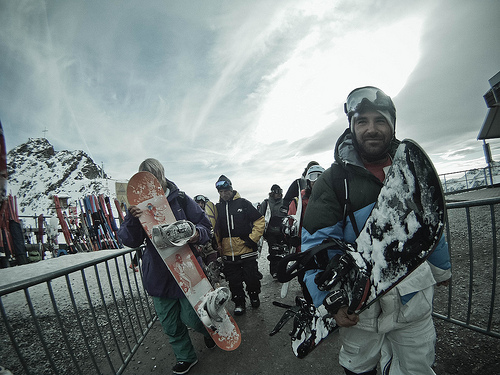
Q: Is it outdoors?
A: Yes, it is outdoors.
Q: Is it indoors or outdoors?
A: It is outdoors.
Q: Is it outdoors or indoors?
A: It is outdoors.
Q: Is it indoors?
A: No, it is outdoors.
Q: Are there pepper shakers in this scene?
A: No, there are no pepper shakers.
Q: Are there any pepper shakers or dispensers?
A: No, there are no pepper shakers or dispensers.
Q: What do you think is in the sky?
A: The clouds are in the sky.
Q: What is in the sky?
A: The clouds are in the sky.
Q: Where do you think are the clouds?
A: The clouds are in the sky.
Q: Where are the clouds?
A: The clouds are in the sky.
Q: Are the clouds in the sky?
A: Yes, the clouds are in the sky.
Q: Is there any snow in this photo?
A: Yes, there is snow.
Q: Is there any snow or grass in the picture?
A: Yes, there is snow.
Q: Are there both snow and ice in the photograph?
A: No, there is snow but no ice.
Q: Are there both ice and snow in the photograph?
A: No, there is snow but no ice.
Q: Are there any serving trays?
A: No, there are no serving trays.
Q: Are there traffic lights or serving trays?
A: No, there are no serving trays or traffic lights.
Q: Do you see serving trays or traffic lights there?
A: No, there are no serving trays or traffic lights.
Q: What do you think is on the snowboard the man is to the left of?
A: The snow is on the snowboard.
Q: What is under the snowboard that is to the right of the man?
A: The snow is under the snowboard.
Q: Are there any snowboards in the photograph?
A: Yes, there is a snowboard.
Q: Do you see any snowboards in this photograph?
A: Yes, there is a snowboard.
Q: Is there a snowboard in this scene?
A: Yes, there is a snowboard.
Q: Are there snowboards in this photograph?
A: Yes, there is a snowboard.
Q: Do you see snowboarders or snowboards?
A: Yes, there is a snowboard.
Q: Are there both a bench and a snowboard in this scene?
A: No, there is a snowboard but no benches.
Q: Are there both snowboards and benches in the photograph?
A: No, there is a snowboard but no benches.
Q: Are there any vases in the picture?
A: No, there are no vases.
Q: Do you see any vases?
A: No, there are no vases.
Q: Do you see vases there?
A: No, there are no vases.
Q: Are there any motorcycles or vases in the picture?
A: No, there are no vases or motorcycles.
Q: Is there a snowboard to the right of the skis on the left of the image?
A: Yes, there is a snowboard to the right of the skis.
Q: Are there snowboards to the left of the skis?
A: No, the snowboard is to the right of the skis.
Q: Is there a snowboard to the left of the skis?
A: No, the snowboard is to the right of the skis.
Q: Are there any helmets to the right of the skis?
A: No, there is a snowboard to the right of the skis.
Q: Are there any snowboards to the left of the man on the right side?
A: Yes, there is a snowboard to the left of the man.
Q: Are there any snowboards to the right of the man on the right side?
A: No, the snowboard is to the left of the man.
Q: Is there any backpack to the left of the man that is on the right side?
A: No, there is a snowboard to the left of the man.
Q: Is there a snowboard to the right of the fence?
A: Yes, there is a snowboard to the right of the fence.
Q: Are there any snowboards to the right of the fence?
A: Yes, there is a snowboard to the right of the fence.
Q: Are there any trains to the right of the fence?
A: No, there is a snowboard to the right of the fence.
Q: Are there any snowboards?
A: Yes, there is a snowboard.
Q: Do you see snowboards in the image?
A: Yes, there is a snowboard.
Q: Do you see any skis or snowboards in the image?
A: Yes, there is a snowboard.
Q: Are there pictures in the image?
A: No, there are no pictures.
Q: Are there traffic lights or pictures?
A: No, there are no pictures or traffic lights.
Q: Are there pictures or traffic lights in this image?
A: No, there are no pictures or traffic lights.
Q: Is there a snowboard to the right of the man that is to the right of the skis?
A: Yes, there is a snowboard to the right of the man.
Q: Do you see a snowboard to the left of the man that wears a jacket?
A: No, the snowboard is to the right of the man.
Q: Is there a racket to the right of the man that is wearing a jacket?
A: No, there is a snowboard to the right of the man.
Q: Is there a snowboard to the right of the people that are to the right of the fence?
A: Yes, there is a snowboard to the right of the people.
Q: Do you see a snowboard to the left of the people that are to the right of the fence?
A: No, the snowboard is to the right of the people.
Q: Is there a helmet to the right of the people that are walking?
A: No, there is a snowboard to the right of the people.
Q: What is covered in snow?
A: The snowboard is covered in snow.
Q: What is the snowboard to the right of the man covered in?
A: The snowboard is covered in snow.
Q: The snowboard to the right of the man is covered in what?
A: The snowboard is covered in snow.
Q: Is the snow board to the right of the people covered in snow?
A: Yes, the snowboard is covered in snow.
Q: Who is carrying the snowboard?
A: The man is carrying the snowboard.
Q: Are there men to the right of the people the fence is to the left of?
A: Yes, there is a man to the right of the people.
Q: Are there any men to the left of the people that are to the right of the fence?
A: No, the man is to the right of the people.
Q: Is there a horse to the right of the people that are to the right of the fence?
A: No, there is a man to the right of the people.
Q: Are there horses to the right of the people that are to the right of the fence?
A: No, there is a man to the right of the people.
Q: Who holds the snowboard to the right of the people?
A: The man holds the snowboard.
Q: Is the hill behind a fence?
A: Yes, the hill is behind a fence.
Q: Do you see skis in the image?
A: Yes, there are skis.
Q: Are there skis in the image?
A: Yes, there are skis.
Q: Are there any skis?
A: Yes, there are skis.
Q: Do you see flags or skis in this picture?
A: Yes, there are skis.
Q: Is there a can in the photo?
A: No, there are no cans.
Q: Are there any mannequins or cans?
A: No, there are no cans or mannequins.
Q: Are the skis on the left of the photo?
A: Yes, the skis are on the left of the image.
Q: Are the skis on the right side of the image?
A: No, the skis are on the left of the image.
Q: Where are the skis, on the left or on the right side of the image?
A: The skis are on the left of the image.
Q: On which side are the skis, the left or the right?
A: The skis are on the left of the image.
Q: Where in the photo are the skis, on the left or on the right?
A: The skis are on the left of the image.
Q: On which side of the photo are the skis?
A: The skis are on the left of the image.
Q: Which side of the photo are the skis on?
A: The skis are on the left of the image.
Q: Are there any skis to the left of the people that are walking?
A: Yes, there are skis to the left of the people.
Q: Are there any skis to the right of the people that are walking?
A: No, the skis are to the left of the people.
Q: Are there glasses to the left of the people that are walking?
A: No, there are skis to the left of the people.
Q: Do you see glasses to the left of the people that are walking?
A: No, there are skis to the left of the people.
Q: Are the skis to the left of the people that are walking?
A: Yes, the skis are to the left of the people.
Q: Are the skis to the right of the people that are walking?
A: No, the skis are to the left of the people.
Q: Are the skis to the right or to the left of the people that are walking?
A: The skis are to the left of the people.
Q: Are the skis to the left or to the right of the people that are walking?
A: The skis are to the left of the people.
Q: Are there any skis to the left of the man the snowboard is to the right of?
A: Yes, there are skis to the left of the man.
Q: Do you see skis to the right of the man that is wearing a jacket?
A: No, the skis are to the left of the man.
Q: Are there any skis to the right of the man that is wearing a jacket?
A: No, the skis are to the left of the man.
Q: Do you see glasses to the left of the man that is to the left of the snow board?
A: No, there are skis to the left of the man.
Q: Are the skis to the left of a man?
A: Yes, the skis are to the left of a man.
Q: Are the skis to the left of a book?
A: No, the skis are to the left of a man.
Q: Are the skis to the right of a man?
A: No, the skis are to the left of a man.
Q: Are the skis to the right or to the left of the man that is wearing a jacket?
A: The skis are to the left of the man.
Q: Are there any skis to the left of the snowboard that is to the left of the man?
A: Yes, there are skis to the left of the snow board.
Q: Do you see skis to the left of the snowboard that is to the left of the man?
A: Yes, there are skis to the left of the snow board.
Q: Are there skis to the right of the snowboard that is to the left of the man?
A: No, the skis are to the left of the snowboard.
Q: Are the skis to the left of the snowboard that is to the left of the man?
A: Yes, the skis are to the left of the snowboard.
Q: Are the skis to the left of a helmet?
A: No, the skis are to the left of the snowboard.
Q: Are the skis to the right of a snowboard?
A: No, the skis are to the left of a snowboard.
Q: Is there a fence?
A: Yes, there is a fence.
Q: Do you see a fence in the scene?
A: Yes, there is a fence.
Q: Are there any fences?
A: Yes, there is a fence.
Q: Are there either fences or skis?
A: Yes, there is a fence.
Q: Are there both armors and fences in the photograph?
A: No, there is a fence but no armors.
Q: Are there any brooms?
A: No, there are no brooms.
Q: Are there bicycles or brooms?
A: No, there are no brooms or bicycles.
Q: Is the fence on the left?
A: Yes, the fence is on the left of the image.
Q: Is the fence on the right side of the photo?
A: No, the fence is on the left of the image.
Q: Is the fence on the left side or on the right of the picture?
A: The fence is on the left of the image.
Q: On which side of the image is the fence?
A: The fence is on the left of the image.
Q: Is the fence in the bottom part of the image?
A: Yes, the fence is in the bottom of the image.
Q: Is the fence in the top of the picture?
A: No, the fence is in the bottom of the image.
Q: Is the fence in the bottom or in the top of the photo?
A: The fence is in the bottom of the image.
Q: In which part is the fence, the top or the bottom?
A: The fence is in the bottom of the image.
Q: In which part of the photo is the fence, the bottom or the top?
A: The fence is in the bottom of the image.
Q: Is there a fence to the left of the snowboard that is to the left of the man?
A: Yes, there is a fence to the left of the snowboard.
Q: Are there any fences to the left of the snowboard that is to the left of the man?
A: Yes, there is a fence to the left of the snowboard.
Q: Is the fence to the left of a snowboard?
A: Yes, the fence is to the left of a snowboard.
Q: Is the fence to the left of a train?
A: No, the fence is to the left of a snowboard.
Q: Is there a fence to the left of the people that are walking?
A: Yes, there is a fence to the left of the people.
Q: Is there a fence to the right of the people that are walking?
A: No, the fence is to the left of the people.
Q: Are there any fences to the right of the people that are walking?
A: No, the fence is to the left of the people.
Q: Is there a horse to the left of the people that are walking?
A: No, there is a fence to the left of the people.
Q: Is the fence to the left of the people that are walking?
A: Yes, the fence is to the left of the people.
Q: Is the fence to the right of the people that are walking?
A: No, the fence is to the left of the people.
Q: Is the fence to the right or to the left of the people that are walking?
A: The fence is to the left of the people.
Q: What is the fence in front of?
A: The fence is in front of the hill.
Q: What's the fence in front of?
A: The fence is in front of the hill.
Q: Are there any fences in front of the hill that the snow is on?
A: Yes, there is a fence in front of the hill.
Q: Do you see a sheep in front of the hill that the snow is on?
A: No, there is a fence in front of the hill.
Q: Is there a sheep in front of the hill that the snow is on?
A: No, there is a fence in front of the hill.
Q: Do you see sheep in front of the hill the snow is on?
A: No, there is a fence in front of the hill.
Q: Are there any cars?
A: No, there are no cars.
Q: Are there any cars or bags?
A: No, there are no cars or bags.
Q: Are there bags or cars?
A: No, there are no cars or bags.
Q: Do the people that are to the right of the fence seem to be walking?
A: Yes, the people are walking.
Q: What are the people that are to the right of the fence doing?
A: The people are walking.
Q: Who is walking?
A: The people are walking.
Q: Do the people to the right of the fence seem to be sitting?
A: No, the people are walking.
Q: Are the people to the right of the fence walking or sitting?
A: The people are walking.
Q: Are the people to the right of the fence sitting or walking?
A: The people are walking.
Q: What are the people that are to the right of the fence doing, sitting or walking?
A: The people are walking.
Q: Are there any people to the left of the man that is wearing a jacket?
A: Yes, there are people to the left of the man.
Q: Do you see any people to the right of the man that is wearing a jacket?
A: No, the people are to the left of the man.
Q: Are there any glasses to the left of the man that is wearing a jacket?
A: No, there are people to the left of the man.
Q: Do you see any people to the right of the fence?
A: Yes, there are people to the right of the fence.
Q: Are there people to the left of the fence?
A: No, the people are to the right of the fence.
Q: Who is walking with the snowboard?
A: The people are walking with the snowboard.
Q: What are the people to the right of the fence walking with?
A: The people are walking with a snowboard.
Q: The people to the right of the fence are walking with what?
A: The people are walking with a snowboard.